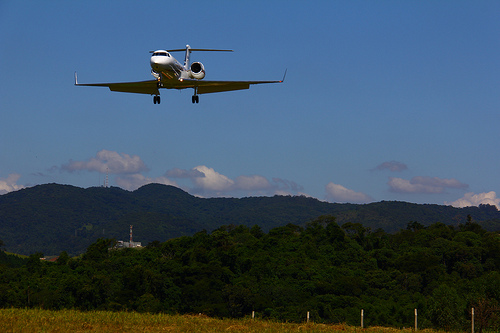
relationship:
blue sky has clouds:
[1, 0, 498, 197] [63, 147, 147, 176]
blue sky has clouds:
[1, 0, 498, 197] [189, 160, 230, 193]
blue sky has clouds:
[1, 0, 498, 197] [326, 179, 369, 204]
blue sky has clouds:
[1, 0, 498, 197] [454, 182, 499, 206]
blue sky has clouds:
[1, 0, 498, 197] [238, 174, 288, 191]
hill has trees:
[0, 180, 497, 264] [0, 182, 498, 267]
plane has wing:
[64, 31, 303, 106] [203, 75, 285, 93]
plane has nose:
[71, 43, 289, 106] [158, 48, 170, 66]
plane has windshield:
[71, 43, 289, 106] [148, 47, 170, 60]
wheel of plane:
[187, 90, 206, 111] [144, 50, 219, 177]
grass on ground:
[147, 305, 199, 325] [128, 309, 210, 333]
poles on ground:
[260, 293, 477, 330] [208, 311, 227, 326]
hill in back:
[0, 181, 499, 260] [216, 104, 429, 223]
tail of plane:
[159, 43, 234, 54] [70, 41, 290, 104]